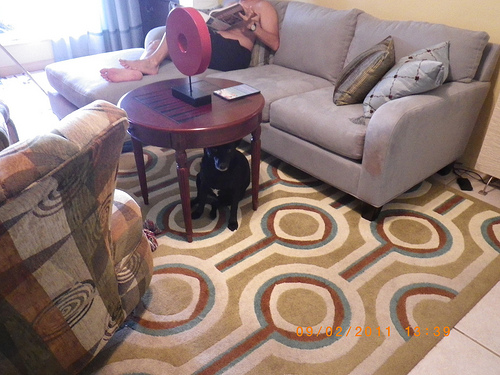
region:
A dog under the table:
[191, 145, 251, 230]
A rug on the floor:
[97, 147, 497, 374]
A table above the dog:
[118, 78, 265, 242]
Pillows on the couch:
[333, 37, 447, 122]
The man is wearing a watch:
[247, 20, 257, 31]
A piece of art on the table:
[164, 6, 211, 106]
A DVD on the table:
[215, 82, 260, 99]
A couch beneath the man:
[50, 0, 499, 218]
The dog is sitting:
[189, 139, 250, 230]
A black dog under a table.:
[192, 144, 252, 233]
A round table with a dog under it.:
[113, 78, 265, 242]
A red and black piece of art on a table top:
[164, 5, 213, 105]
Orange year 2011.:
[355, 326, 392, 338]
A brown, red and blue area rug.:
[91, 175, 499, 372]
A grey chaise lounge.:
[48, 0, 498, 218]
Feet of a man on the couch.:
[97, 59, 164, 82]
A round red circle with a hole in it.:
[164, 6, 212, 76]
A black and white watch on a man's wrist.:
[248, 22, 258, 34]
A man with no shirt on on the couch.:
[99, 0, 279, 86]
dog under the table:
[154, 105, 279, 234]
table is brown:
[130, 104, 264, 216]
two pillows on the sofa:
[316, 63, 476, 102]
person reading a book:
[207, 0, 291, 69]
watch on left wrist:
[244, 19, 274, 37]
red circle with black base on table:
[169, 6, 206, 111]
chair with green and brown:
[0, 124, 145, 367]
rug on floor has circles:
[177, 222, 445, 374]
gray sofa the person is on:
[281, 8, 471, 171]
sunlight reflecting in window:
[2, 0, 105, 90]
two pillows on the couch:
[318, 42, 467, 126]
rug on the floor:
[11, 68, 498, 373]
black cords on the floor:
[448, 165, 487, 193]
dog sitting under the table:
[176, 133, 273, 230]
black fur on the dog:
[178, 135, 260, 240]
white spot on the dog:
[211, 184, 221, 199]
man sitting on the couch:
[101, 0, 288, 86]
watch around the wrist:
[246, 22, 258, 34]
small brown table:
[110, 68, 282, 248]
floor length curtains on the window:
[40, 0, 152, 62]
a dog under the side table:
[115, 73, 270, 245]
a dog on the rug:
[188, 140, 252, 235]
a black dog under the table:
[185, 135, 252, 234]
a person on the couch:
[96, 0, 281, 84]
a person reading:
[96, 1, 281, 85]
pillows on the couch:
[330, 30, 455, 120]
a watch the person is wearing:
[246, 19, 258, 33]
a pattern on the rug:
[373, 270, 462, 344]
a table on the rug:
[118, 76, 268, 243]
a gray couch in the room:
[42, 2, 498, 227]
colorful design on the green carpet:
[240, 260, 360, 362]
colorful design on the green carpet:
[370, 270, 452, 350]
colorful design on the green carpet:
[350, 197, 460, 275]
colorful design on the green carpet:
[463, 202, 498, 260]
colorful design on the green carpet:
[115, 255, 230, 348]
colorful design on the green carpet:
[258, 196, 348, 264]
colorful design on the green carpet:
[161, 195, 234, 256]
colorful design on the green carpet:
[265, 155, 316, 198]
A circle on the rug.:
[238, 257, 360, 357]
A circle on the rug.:
[370, 263, 446, 327]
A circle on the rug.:
[366, 195, 444, 261]